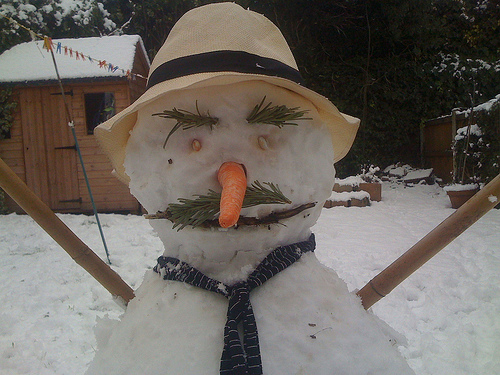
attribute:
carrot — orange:
[210, 162, 247, 228]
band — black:
[160, 55, 288, 74]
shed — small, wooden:
[0, 32, 150, 216]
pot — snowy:
[448, 180, 498, 215]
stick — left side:
[2, 157, 157, 317]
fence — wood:
[391, 100, 499, 202]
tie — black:
[156, 252, 323, 367]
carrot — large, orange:
[212, 157, 249, 231]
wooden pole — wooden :
[367, 183, 478, 293]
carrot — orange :
[220, 166, 242, 223]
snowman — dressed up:
[8, 2, 475, 373]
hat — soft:
[143, 0, 320, 110]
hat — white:
[101, 3, 360, 173]